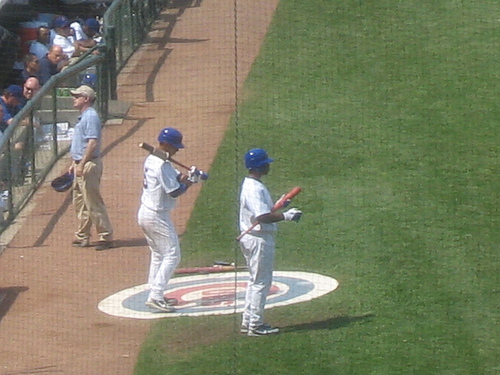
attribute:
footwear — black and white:
[233, 309, 283, 345]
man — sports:
[235, 144, 302, 339]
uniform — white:
[240, 179, 276, 325]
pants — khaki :
[67, 159, 115, 242]